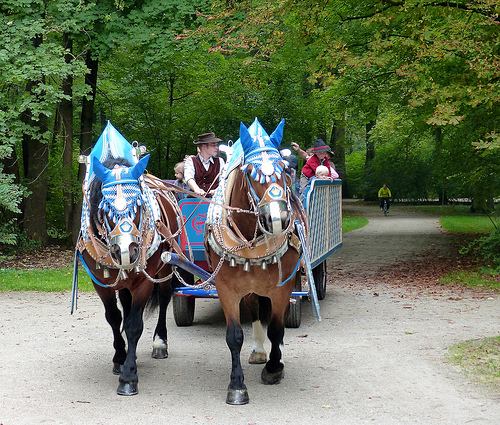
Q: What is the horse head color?
A: Blue.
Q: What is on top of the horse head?
A: Decoration.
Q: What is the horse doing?
A: Pulling a cart.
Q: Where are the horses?
A: In a park.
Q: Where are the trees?
A: Behind the carriage.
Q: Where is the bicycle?
A: Behind the carriage.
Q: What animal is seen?
A: Horse.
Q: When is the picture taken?
A: Daytime.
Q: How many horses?
A: 2.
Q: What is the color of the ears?
A: Blue.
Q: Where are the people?
A: In the cart.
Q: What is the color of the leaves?
A: Green.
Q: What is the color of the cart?
A: Blue and white.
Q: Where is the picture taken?
A: In the countryside.